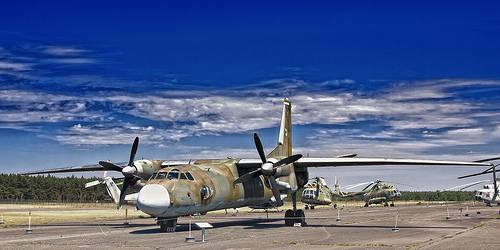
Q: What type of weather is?
A: It is cloudy.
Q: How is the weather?
A: It is cloudy.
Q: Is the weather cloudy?
A: Yes, it is cloudy.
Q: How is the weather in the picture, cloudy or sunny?
A: It is cloudy.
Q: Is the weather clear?
A: No, it is cloudy.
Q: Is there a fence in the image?
A: Yes, there is a fence.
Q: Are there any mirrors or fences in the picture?
A: Yes, there is a fence.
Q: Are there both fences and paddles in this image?
A: No, there is a fence but no paddles.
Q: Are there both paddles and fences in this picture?
A: No, there is a fence but no paddles.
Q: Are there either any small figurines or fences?
A: Yes, there is a small fence.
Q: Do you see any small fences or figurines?
A: Yes, there is a small fence.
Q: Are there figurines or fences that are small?
A: Yes, the fence is small.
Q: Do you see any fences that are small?
A: Yes, there is a small fence.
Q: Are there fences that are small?
A: Yes, there is a fence that is small.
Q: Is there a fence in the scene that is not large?
A: Yes, there is a small fence.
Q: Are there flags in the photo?
A: No, there are no flags.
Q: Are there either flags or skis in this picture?
A: No, there are no flags or skis.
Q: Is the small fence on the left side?
A: Yes, the fence is on the left of the image.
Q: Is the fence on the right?
A: No, the fence is on the left of the image.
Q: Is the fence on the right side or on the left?
A: The fence is on the left of the image.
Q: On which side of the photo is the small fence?
A: The fence is on the left of the image.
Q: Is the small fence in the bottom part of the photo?
A: Yes, the fence is in the bottom of the image.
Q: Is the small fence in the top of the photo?
A: No, the fence is in the bottom of the image.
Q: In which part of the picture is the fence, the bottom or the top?
A: The fence is in the bottom of the image.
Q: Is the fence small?
A: Yes, the fence is small.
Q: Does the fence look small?
A: Yes, the fence is small.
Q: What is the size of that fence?
A: The fence is small.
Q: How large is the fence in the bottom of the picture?
A: The fence is small.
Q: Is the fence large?
A: No, the fence is small.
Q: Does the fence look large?
A: No, the fence is small.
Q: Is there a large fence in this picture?
A: No, there is a fence but it is small.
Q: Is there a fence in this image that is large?
A: No, there is a fence but it is small.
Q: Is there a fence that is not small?
A: No, there is a fence but it is small.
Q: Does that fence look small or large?
A: The fence is small.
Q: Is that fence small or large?
A: The fence is small.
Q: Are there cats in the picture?
A: No, there are no cats.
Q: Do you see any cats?
A: No, there are no cats.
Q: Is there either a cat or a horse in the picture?
A: No, there are no cats or horses.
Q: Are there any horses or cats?
A: No, there are no cats or horses.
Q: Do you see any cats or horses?
A: No, there are no cats or horses.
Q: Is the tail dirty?
A: Yes, the tail is dirty.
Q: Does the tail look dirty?
A: Yes, the tail is dirty.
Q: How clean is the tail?
A: The tail is dirty.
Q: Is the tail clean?
A: No, the tail is dirty.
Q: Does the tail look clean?
A: No, the tail is dirty.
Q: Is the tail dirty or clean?
A: The tail is dirty.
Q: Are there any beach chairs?
A: No, there are no beach chairs.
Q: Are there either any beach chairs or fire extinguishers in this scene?
A: No, there are no beach chairs or fire extinguishers.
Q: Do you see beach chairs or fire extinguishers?
A: No, there are no beach chairs or fire extinguishers.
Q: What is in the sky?
A: The clouds are in the sky.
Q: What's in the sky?
A: The clouds are in the sky.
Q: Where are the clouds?
A: The clouds are in the sky.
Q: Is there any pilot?
A: No, there are no pilots.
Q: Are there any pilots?
A: No, there are no pilots.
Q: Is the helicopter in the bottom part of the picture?
A: Yes, the helicopter is in the bottom of the image.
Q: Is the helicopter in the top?
A: No, the helicopter is in the bottom of the image.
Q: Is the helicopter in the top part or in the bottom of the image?
A: The helicopter is in the bottom of the image.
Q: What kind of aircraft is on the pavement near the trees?
A: The aircraft is a helicopter.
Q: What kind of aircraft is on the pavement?
A: The aircraft is a helicopter.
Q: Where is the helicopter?
A: The helicopter is on the pavement.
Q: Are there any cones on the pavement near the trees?
A: No, there is a helicopter on the pavement.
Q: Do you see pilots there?
A: No, there are no pilots.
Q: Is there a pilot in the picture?
A: No, there are no pilots.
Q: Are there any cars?
A: No, there are no cars.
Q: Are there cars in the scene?
A: No, there are no cars.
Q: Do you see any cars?
A: No, there are no cars.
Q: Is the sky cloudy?
A: Yes, the sky is cloudy.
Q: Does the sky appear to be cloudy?
A: Yes, the sky is cloudy.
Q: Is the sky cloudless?
A: No, the sky is cloudy.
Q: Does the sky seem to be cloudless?
A: No, the sky is cloudy.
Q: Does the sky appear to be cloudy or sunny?
A: The sky is cloudy.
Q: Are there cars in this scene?
A: No, there are no cars.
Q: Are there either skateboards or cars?
A: No, there are no cars or skateboards.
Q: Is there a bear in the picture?
A: No, there are no bears.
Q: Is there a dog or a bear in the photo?
A: No, there are no bears or dogs.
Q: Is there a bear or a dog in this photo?
A: No, there are no bears or dogs.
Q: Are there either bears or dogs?
A: No, there are no bears or dogs.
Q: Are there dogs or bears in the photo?
A: No, there are no bears or dogs.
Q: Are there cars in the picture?
A: No, there are no cars.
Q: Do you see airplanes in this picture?
A: Yes, there is an airplane.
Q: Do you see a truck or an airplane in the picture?
A: Yes, there is an airplane.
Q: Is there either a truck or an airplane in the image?
A: Yes, there is an airplane.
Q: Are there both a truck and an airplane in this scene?
A: No, there is an airplane but no trucks.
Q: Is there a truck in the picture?
A: No, there are no trucks.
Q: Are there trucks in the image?
A: No, there are no trucks.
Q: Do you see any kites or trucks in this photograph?
A: No, there are no trucks or kites.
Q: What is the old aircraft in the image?
A: The aircraft is an airplane.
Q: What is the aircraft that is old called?
A: The aircraft is an airplane.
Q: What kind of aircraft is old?
A: The aircraft is an airplane.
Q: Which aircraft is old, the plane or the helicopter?
A: The plane is old.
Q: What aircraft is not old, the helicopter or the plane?
A: The helicopter is not old.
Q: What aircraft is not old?
A: The aircraft is a helicopter.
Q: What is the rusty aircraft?
A: The aircraft is an airplane.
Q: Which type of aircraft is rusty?
A: The aircraft is an airplane.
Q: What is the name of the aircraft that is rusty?
A: The aircraft is an airplane.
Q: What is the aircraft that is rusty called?
A: The aircraft is an airplane.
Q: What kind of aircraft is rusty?
A: The aircraft is an airplane.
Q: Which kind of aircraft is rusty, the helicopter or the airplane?
A: The airplane is rusty.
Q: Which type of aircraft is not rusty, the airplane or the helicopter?
A: The helicopter is not rusty.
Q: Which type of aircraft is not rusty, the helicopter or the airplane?
A: The helicopter is not rusty.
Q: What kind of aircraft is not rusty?
A: The aircraft is a helicopter.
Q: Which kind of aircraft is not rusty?
A: The aircraft is a helicopter.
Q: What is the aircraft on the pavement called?
A: The aircraft is an airplane.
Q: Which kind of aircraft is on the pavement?
A: The aircraft is an airplane.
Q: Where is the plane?
A: The plane is on the pavement.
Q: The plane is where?
A: The plane is on the pavement.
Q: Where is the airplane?
A: The plane is on the pavement.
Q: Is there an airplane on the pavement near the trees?
A: Yes, there is an airplane on the pavement.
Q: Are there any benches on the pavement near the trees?
A: No, there is an airplane on the pavement.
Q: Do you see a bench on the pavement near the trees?
A: No, there is an airplane on the pavement.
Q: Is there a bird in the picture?
A: No, there are no birds.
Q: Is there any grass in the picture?
A: Yes, there is grass.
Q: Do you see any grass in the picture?
A: Yes, there is grass.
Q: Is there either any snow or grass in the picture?
A: Yes, there is grass.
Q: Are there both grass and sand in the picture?
A: No, there is grass but no sand.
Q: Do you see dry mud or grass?
A: Yes, there is dry grass.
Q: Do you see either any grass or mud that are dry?
A: Yes, the grass is dry.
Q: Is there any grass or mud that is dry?
A: Yes, the grass is dry.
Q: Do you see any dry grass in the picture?
A: Yes, there is dry grass.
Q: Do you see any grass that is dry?
A: Yes, there is grass that is dry.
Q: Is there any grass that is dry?
A: Yes, there is grass that is dry.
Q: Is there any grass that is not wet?
A: Yes, there is dry grass.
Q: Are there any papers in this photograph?
A: No, there are no papers.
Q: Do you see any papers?
A: No, there are no papers.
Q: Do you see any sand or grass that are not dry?
A: No, there is grass but it is dry.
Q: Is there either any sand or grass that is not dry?
A: No, there is grass but it is dry.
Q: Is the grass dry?
A: Yes, the grass is dry.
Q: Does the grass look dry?
A: Yes, the grass is dry.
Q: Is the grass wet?
A: No, the grass is dry.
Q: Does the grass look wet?
A: No, the grass is dry.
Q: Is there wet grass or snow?
A: No, there is grass but it is dry.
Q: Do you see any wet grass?
A: No, there is grass but it is dry.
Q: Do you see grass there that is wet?
A: No, there is grass but it is dry.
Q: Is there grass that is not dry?
A: No, there is grass but it is dry.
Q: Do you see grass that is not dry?
A: No, there is grass but it is dry.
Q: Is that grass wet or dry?
A: The grass is dry.